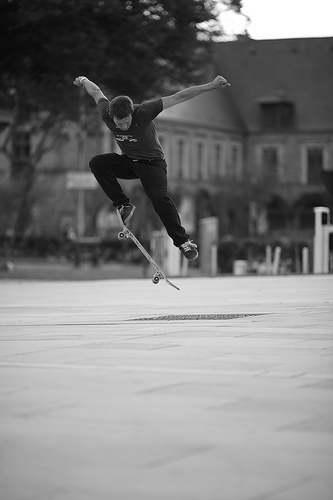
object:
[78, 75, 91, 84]
watch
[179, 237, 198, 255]
laces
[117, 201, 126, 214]
laces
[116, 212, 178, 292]
skateboard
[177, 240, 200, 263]
tennis shoe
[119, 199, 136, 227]
tennis shoe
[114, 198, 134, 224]
man's foot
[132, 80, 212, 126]
arm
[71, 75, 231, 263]
boy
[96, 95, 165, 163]
t-shirt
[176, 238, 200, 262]
man's foot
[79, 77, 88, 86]
wrist